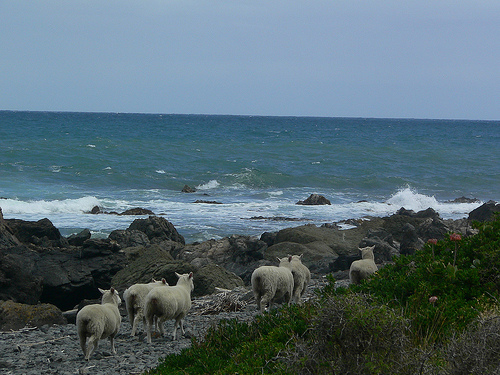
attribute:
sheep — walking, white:
[76, 285, 123, 358]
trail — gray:
[1, 243, 350, 372]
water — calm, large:
[2, 112, 500, 200]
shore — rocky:
[3, 186, 500, 241]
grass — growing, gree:
[143, 216, 500, 373]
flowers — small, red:
[427, 233, 462, 268]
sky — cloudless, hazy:
[1, 1, 499, 124]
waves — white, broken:
[1, 184, 499, 219]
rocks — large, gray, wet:
[87, 184, 481, 221]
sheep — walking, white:
[250, 266, 296, 308]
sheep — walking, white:
[346, 243, 379, 279]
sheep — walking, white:
[288, 252, 310, 297]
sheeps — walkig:
[77, 245, 378, 360]